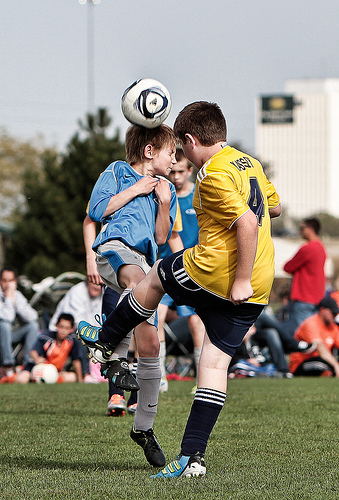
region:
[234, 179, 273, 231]
Number four on boy's jersey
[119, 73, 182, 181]
Soccer ball on boy's head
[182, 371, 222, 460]
Black and white socks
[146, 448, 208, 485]
Blue, black, white, and yellow shoes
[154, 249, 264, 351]
Black shorts with white stripes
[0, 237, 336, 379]
People watching soccer game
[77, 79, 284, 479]
Three boys playing soccer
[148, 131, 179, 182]
Boy's pained facial expression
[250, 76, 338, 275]
Large white building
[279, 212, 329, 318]
Man turned away from the game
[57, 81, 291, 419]
boys that are playing soccer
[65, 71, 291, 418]
boys wearing soccer uniform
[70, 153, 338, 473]
boys that are wearing cleats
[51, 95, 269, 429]
boys wearing lons socks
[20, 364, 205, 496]
a field of grass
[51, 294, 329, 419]
people sittin gon the grass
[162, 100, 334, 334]
a boy wearing a yellow jersey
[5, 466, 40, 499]
Small patch of short green grass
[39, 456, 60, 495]
Small patch of short green grass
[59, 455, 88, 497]
Small patch of short green grass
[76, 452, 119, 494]
Small patch of short green grass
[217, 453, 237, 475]
Small patch of short green grass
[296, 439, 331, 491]
Small patch of short green grass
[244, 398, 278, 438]
Small patch of short green grass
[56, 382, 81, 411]
Small patch of short green grass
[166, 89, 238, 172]
head of a person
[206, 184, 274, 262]
arm of a person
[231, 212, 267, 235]
elbow of a person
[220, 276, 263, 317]
hand of a person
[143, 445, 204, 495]
feet of a person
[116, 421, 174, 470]
feet of a person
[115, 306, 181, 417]
leg of a person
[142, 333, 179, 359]
knee of a person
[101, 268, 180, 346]
leg of a person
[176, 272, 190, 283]
white stripe on shorts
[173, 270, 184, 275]
white stripe on shorts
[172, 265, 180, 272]
white stripe on shorts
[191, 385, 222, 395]
white stripe on socks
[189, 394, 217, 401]
white stripe on socks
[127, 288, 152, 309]
white stripe on socks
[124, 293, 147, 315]
white stripe on socks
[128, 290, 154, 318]
white stripes on socks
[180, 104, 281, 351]
boy wearing a yellow shirt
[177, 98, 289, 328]
boy wearing black shorts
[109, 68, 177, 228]
boy with ball on his head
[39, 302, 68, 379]
boy watching soccer game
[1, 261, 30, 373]
man watching soccer game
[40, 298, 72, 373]
boy wearing orange shirt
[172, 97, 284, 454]
boy wearing black socks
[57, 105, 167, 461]
boy wearing black shoes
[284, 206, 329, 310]
man wearing red shirt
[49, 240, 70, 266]
green leaves on the tree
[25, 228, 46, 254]
green leaves on the tree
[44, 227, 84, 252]
green leaves on the tree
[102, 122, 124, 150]
green leaves on the tree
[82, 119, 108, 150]
green leaves on the tree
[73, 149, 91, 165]
green leaves on the tree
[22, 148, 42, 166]
green leaves on the treegreen leaves on the tree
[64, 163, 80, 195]
green leaves on the tree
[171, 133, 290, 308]
the shirt is yellow